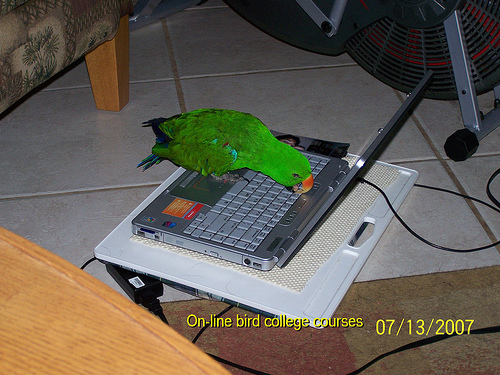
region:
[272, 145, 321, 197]
the head of a bird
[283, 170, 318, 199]
the beak of a bird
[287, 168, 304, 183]
the eye of a bird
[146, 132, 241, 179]
the wing of a bird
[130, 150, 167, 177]
the tail of a bird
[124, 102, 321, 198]
a large green bird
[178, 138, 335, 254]
a gray laptop keyboard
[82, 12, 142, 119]
the leg of a chair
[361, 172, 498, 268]
a black computer cord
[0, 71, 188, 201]
a white tile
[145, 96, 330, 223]
bird is on keyboard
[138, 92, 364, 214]
the bird is green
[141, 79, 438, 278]
the laptop is gray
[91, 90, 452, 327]
laptop is on white surface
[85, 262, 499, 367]
black cord around laptop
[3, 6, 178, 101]
chair behind the laptop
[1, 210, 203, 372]
table made of wood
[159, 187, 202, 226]
orange label on laptop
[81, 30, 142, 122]
base of chair made from wood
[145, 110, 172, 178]
ends of feathers are blue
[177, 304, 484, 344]
Picture was taken July 13, 2007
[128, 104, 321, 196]
bird looks like a conure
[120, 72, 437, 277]
conure is sitting on a laptop computer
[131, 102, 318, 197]
conure is mostly a brilliant green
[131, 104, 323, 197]
conure has an orange beak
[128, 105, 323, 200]
conure has blue tail feathers and wingtips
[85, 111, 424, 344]
looks like the laptop is on a cutting board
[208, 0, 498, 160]
exercise bike behind the laptop and conure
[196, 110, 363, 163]
photograph sitting next to laptop and conure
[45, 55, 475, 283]
laptop and conure are on the floor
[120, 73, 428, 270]
a silver laptop computer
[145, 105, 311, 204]
a green parrot on laptop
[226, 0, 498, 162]
a grey exercise bike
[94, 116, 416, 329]
a white lap pad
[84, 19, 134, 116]
a wooden chair leg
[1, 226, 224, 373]
a brown round table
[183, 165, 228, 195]
a computer track pad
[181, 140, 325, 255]
a computer keyboard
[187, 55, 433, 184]
a white floor tile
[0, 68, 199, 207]
a white floor tile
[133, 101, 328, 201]
medium sized tropical bird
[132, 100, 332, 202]
domesticated parakeet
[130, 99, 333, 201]
bright green bird with orange beak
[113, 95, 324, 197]
brightly colored parakeet with dark blue tailfeathers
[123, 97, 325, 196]
bird pecking at laptop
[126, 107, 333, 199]
bird trying to eat a piece of the laptop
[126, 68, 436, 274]
laptop on which the bird is sitting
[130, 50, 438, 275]
small laptop with grey keyboard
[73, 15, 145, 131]
short wooden leg of couch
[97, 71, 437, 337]
laptop and bird sitting on laptop tray